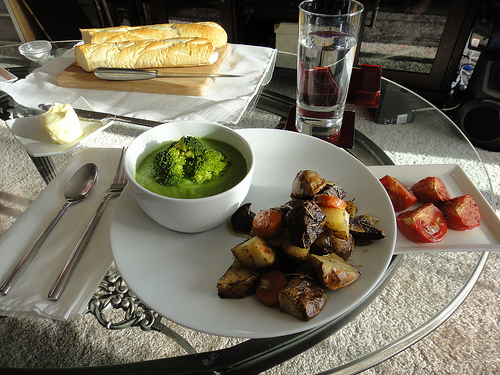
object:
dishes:
[43, 16, 499, 375]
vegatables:
[215, 168, 387, 323]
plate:
[110, 121, 395, 345]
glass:
[291, 0, 360, 141]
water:
[294, 31, 359, 129]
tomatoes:
[377, 175, 482, 246]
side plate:
[361, 162, 499, 256]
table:
[0, 37, 499, 374]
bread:
[73, 21, 228, 72]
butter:
[39, 102, 84, 145]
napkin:
[1, 146, 139, 322]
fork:
[45, 144, 135, 303]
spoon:
[0, 161, 99, 296]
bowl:
[122, 118, 257, 235]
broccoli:
[150, 133, 229, 189]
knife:
[93, 66, 247, 81]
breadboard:
[54, 40, 237, 97]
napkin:
[6, 95, 112, 157]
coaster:
[282, 104, 356, 148]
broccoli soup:
[133, 133, 244, 198]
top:
[64, 162, 101, 204]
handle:
[47, 191, 113, 301]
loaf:
[72, 37, 220, 74]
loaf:
[78, 21, 230, 47]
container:
[16, 39, 51, 63]